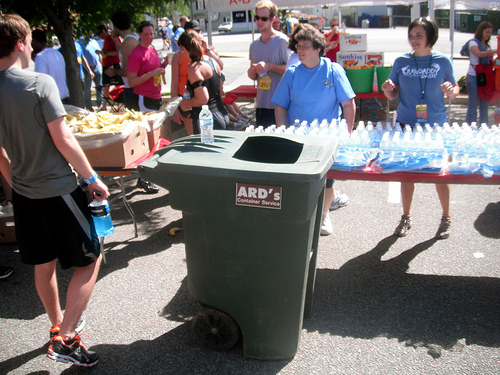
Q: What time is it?
A: Daytime.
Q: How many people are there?
A: More than ten.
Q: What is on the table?
A: Water.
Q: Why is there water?
A: For people to drink.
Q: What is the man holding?
A: A drink.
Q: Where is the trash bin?
A: Next to the water.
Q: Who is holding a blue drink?
A: A guy.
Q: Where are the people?
A: Food court.